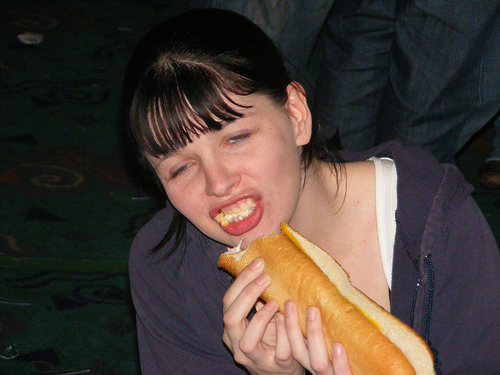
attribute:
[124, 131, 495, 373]
sweater — blue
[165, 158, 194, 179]
eye — close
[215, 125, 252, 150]
eye — close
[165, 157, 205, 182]
eye — squinted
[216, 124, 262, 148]
eye — squinted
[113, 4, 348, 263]
hair — woman's, dark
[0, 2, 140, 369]
carpet — green, patterned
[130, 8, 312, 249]
head — woman's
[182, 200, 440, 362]
hot dog — huge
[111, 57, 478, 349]
woman — dark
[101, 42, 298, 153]
bangs — woman's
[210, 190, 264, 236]
mouth — woman's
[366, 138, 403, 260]
shirt — white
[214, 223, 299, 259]
bite — missing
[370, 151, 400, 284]
t-shirt — white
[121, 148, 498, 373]
top — blue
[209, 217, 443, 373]
hot dog — huge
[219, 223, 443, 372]
sandwich — big